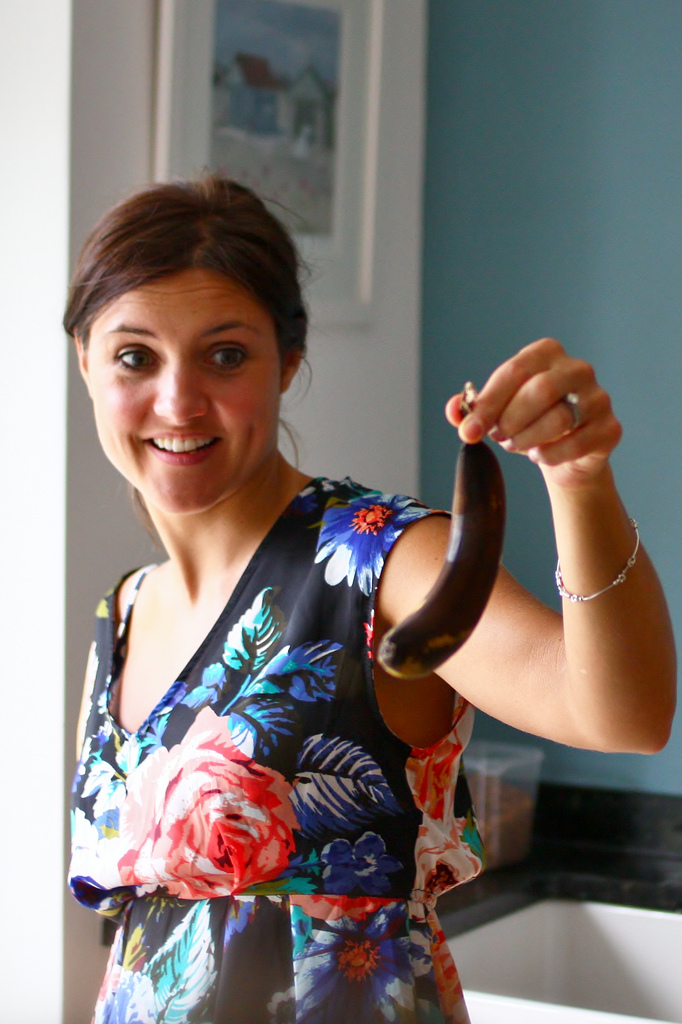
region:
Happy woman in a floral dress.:
[62, 177, 675, 1022]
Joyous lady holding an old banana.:
[63, 166, 676, 1023]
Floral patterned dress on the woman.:
[66, 476, 483, 1022]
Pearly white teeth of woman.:
[154, 435, 215, 452]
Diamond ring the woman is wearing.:
[562, 391, 582, 429]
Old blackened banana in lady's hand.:
[380, 383, 506, 675]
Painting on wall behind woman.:
[154, 0, 385, 328]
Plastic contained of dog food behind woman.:
[460, 736, 545, 868]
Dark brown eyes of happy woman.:
[117, 339, 249, 370]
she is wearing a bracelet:
[556, 550, 631, 617]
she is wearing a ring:
[554, 382, 591, 436]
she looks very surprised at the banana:
[113, 316, 270, 484]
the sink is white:
[550, 919, 624, 965]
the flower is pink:
[173, 764, 262, 851]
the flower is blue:
[319, 928, 400, 1000]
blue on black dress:
[283, 737, 392, 820]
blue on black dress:
[265, 634, 340, 712]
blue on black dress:
[194, 665, 226, 713]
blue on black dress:
[325, 832, 394, 888]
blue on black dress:
[309, 912, 424, 1007]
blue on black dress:
[156, 912, 234, 1016]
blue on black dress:
[332, 485, 411, 581]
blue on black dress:
[80, 769, 126, 806]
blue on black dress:
[103, 738, 156, 763]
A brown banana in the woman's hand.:
[361, 373, 514, 697]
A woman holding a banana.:
[69, 181, 676, 1019]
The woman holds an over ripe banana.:
[359, 343, 676, 783]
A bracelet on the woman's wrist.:
[548, 502, 657, 617]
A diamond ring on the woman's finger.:
[548, 380, 589, 440]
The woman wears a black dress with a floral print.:
[63, 463, 478, 1022]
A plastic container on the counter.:
[467, 732, 549, 863]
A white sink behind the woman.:
[452, 892, 679, 1017]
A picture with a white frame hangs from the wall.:
[156, 3, 396, 335]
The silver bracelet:
[536, 533, 662, 615]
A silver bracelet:
[548, 540, 657, 603]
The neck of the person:
[134, 524, 272, 595]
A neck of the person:
[135, 525, 255, 591]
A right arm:
[370, 528, 675, 775]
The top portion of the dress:
[77, 531, 513, 907]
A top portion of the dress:
[63, 535, 505, 879]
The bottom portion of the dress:
[76, 896, 470, 1021]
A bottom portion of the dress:
[68, 894, 482, 1022]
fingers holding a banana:
[367, 329, 513, 711]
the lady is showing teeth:
[63, 174, 319, 565]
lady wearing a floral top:
[76, 99, 481, 1019]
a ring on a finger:
[546, 386, 601, 435]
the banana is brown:
[351, 356, 524, 701]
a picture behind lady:
[95, 82, 422, 309]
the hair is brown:
[32, 150, 405, 343]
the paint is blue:
[470, 60, 658, 293]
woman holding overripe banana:
[53, 149, 664, 1021]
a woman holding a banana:
[313, 337, 650, 746]